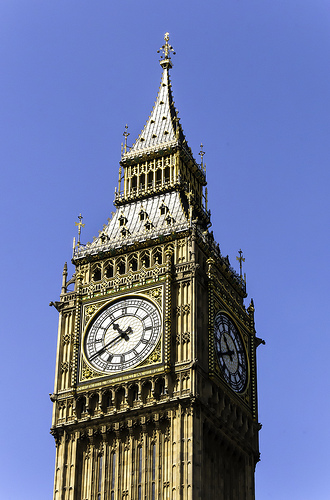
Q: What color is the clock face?
A: White.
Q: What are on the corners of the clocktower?
A: Spires.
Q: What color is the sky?
A: Blue.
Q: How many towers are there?
A: 1.